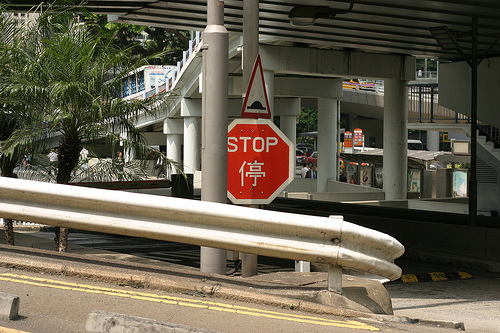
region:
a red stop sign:
[208, 109, 298, 205]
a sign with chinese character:
[215, 110, 304, 216]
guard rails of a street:
[10, 169, 413, 291]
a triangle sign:
[240, 45, 279, 120]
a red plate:
[208, 105, 300, 207]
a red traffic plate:
[200, 107, 305, 201]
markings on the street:
[1, 244, 396, 329]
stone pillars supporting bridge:
[361, 47, 424, 219]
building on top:
[91, 50, 178, 105]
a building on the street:
[318, 118, 468, 203]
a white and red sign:
[228, 116, 294, 201]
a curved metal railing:
[0, 172, 403, 296]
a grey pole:
[200, 0, 230, 273]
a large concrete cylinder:
[384, 78, 409, 204]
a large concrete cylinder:
[316, 98, 339, 194]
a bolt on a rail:
[331, 236, 343, 243]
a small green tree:
[0, 5, 188, 185]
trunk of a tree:
[54, 128, 81, 185]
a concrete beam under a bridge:
[256, 44, 416, 83]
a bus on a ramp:
[103, 64, 175, 96]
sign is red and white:
[216, 116, 317, 226]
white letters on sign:
[226, 128, 283, 160]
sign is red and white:
[239, 51, 289, 131]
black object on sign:
[241, 96, 273, 119]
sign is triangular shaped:
[233, 50, 279, 127]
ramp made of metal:
[3, 161, 408, 306]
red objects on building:
[343, 125, 368, 148]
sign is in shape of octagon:
[217, 110, 301, 210]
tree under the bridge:
[0, 10, 162, 201]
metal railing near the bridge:
[406, 78, 476, 135]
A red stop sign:
[219, 116, 293, 203]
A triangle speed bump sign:
[234, 42, 278, 115]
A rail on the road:
[2, 175, 382, 275]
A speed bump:
[365, 274, 476, 283]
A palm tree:
[59, 30, 115, 174]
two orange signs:
[331, 127, 371, 149]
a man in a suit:
[295, 164, 321, 180]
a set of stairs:
[450, 111, 498, 156]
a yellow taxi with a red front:
[320, 70, 385, 90]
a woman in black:
[100, 150, 132, 165]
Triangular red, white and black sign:
[237, 51, 274, 120]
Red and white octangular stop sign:
[225, 119, 295, 203]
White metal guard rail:
[0, 170, 404, 282]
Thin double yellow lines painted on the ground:
[0, 264, 379, 331]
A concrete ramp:
[2, 238, 466, 332]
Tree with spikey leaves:
[2, 5, 189, 254]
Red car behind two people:
[292, 146, 317, 179]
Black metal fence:
[407, 80, 472, 124]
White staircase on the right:
[462, 118, 499, 158]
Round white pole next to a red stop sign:
[194, 0, 295, 272]